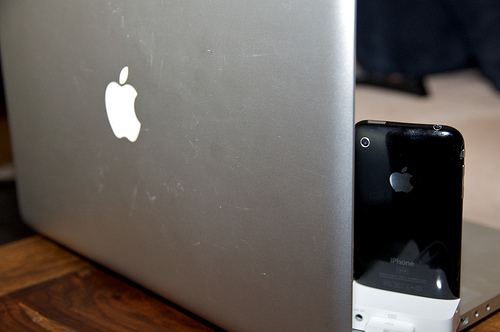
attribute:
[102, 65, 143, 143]
logo — white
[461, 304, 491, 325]
ports — small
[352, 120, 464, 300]
phone — back, black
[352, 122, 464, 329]
phone — cell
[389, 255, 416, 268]
writing — white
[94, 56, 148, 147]
logo — apple, white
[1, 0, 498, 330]
laptop — silver, apple, table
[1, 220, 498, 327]
table — wood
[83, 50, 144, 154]
logo — apple, silver